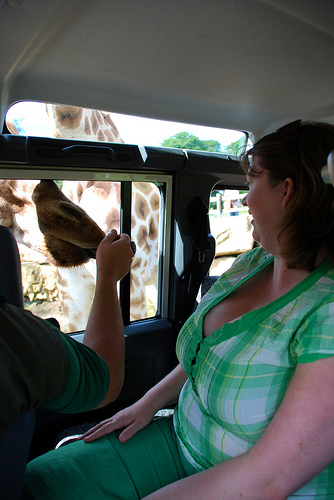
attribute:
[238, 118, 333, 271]
hair — brown, short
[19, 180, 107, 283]
head — shaded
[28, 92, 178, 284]
giraffe — brown , white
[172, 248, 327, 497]
shirt — striped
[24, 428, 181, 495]
pants — green 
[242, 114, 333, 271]
brown hair — brown 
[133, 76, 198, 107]
floor — watching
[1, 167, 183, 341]
window — open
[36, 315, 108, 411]
sleeve — green 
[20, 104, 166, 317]
giraffe — second 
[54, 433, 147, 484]
pants — green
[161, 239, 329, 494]
shirt — white, green 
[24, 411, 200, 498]
pants — green 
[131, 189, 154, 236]
spots — brown 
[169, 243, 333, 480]
shirt — plaid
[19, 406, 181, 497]
pants — green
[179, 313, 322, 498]
green top — plaid , green 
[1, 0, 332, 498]
bus — white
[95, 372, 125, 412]
elbow — bent 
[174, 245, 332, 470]
top — green, white, yellow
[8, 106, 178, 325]
giraffe — tall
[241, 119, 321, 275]
hair — dark brown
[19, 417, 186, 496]
pants — green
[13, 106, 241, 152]
sunlight — bright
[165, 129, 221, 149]
tops — tree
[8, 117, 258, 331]
park — wild animal